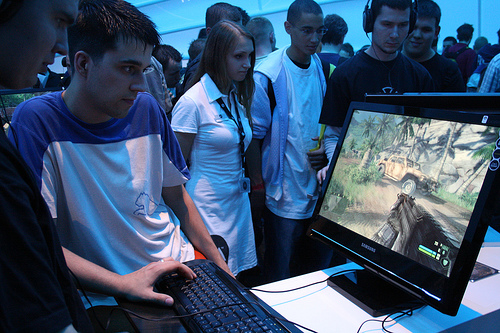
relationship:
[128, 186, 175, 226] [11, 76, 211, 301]
logo on shirt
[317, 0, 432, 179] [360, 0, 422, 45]
boy wearing headphones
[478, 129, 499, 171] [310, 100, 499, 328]
stickers on computer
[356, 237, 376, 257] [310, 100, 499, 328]
samsung logo on computer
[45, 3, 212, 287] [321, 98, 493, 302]
guy looking in monitor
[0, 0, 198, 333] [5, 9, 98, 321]
man in black dress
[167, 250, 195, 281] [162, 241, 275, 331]
finger on keyboard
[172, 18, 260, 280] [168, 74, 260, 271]
girl in dress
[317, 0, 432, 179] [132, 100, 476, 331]
boy behind computer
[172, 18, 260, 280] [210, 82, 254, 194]
girl wearing tag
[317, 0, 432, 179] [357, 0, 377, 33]
boy wearing headphones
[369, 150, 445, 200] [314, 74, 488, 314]
jeep on screen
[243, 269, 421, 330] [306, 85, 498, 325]
wires attached to monitor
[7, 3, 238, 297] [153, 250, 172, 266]
guy wearing ring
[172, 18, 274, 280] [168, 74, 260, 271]
girl has dress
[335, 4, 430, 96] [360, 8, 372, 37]
boy has headphones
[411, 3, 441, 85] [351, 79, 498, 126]
person watching computer monitor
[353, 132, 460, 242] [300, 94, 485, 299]
fps on screen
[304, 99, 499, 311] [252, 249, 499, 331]
screen on whitedesk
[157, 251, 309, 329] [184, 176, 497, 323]
keyboard on desk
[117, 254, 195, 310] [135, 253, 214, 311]
hand of man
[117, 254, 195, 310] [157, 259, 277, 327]
hand pushing keyboard